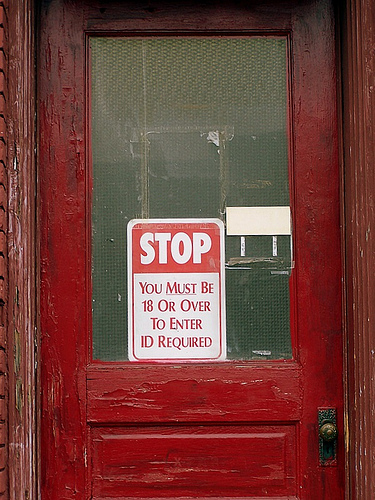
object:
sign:
[126, 217, 228, 365]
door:
[38, 0, 347, 499]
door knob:
[316, 407, 339, 465]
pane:
[84, 35, 300, 362]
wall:
[0, 1, 12, 499]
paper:
[225, 203, 294, 238]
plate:
[319, 404, 337, 462]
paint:
[324, 457, 337, 469]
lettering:
[139, 278, 213, 351]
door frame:
[9, 2, 45, 496]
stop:
[139, 229, 211, 265]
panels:
[69, 365, 310, 498]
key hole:
[323, 443, 332, 456]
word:
[165, 280, 200, 296]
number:
[142, 298, 155, 314]